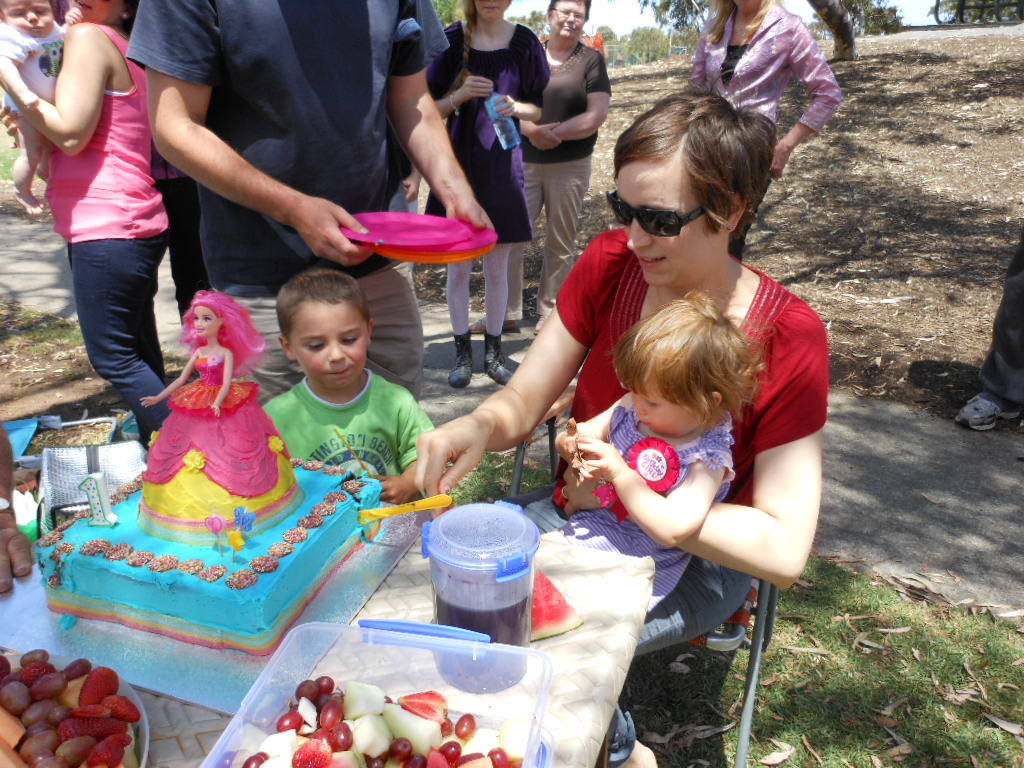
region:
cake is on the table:
[35, 285, 396, 659]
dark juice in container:
[415, 501, 561, 697]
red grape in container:
[291, 676, 318, 699]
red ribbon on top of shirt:
[603, 437, 689, 518]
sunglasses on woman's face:
[594, 188, 721, 243]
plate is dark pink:
[331, 210, 494, 249]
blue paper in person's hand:
[486, 87, 525, 146]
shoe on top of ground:
[953, 384, 1012, 438]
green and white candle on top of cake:
[77, 472, 122, 531]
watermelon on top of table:
[534, 570, 591, 650]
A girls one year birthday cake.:
[38, 288, 374, 647]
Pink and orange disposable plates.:
[336, 209, 501, 261]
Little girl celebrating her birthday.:
[538, 297, 764, 617]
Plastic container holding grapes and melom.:
[242, 635, 552, 766]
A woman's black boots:
[440, 322, 523, 396]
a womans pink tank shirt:
[51, 38, 157, 253]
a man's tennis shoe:
[949, 392, 1014, 444]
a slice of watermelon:
[522, 570, 577, 650]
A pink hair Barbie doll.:
[141, 266, 298, 523]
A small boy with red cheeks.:
[231, 269, 440, 478]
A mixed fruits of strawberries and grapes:
[10, 651, 144, 765]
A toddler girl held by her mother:
[557, 294, 731, 554]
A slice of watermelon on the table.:
[528, 568, 586, 633]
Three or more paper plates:
[342, 206, 514, 267]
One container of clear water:
[481, 76, 530, 176]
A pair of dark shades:
[598, 187, 700, 236]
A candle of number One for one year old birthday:
[73, 465, 121, 530]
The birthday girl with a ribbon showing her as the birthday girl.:
[582, 304, 756, 565]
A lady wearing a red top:
[562, 82, 826, 457]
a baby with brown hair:
[569, 300, 759, 557]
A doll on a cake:
[136, 281, 295, 558]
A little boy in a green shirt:
[265, 257, 428, 491]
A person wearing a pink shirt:
[41, 3, 166, 250]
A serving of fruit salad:
[283, 667, 392, 760]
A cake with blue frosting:
[27, 455, 398, 655]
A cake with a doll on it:
[44, 288, 386, 674]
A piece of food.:
[316, 694, 346, 726]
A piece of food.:
[345, 681, 369, 708]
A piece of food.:
[357, 708, 389, 744]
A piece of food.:
[60, 656, 96, 675]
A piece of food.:
[63, 715, 136, 736]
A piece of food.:
[98, 687, 137, 714]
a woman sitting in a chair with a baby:
[407, 88, 822, 766]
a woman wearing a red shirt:
[427, 88, 830, 766]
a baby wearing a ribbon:
[487, 297, 722, 624]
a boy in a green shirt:
[256, 265, 435, 488]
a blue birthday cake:
[40, 287, 385, 660]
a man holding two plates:
[129, 2, 500, 392]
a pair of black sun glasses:
[607, 190, 703, 236]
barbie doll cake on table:
[11, 251, 436, 686]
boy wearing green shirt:
[239, 245, 440, 569]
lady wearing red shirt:
[484, 54, 883, 766]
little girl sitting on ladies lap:
[488, 295, 793, 586]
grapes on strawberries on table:
[4, 598, 176, 764]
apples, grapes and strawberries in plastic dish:
[171, 601, 644, 766]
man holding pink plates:
[279, 169, 578, 326]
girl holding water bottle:
[443, 2, 595, 408]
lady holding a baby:
[0, 2, 223, 296]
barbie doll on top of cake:
[125, 280, 315, 541]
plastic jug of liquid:
[408, 492, 548, 701]